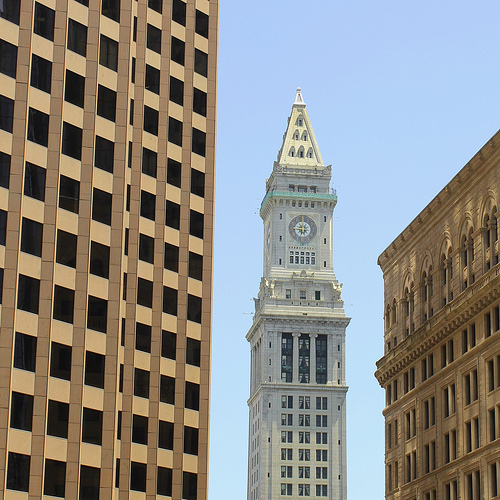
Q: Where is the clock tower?
A: Between two buildings.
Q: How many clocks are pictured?
A: One.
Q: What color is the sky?
A: Blue.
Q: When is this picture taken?
A: Daytime.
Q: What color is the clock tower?
A: White.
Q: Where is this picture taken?
A: A city.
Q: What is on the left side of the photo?
A: A building.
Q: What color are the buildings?
A: Tan.